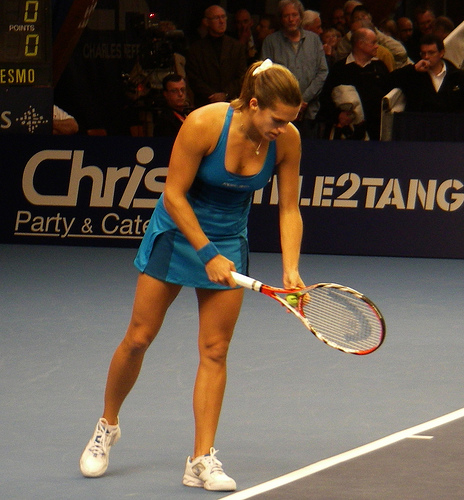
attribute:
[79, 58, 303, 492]
woman — playing, preparing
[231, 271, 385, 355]
racket — present, red, white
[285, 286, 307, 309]
tennis ball — green, present, yellow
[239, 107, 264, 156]
necklace — gold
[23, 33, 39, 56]
points — green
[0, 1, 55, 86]
scoreboard — yellow, black, present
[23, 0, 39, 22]
points — green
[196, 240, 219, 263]
wristband — blue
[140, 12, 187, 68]
camera — recording, filming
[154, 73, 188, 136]
man — sitting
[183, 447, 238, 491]
sneaker — white, grey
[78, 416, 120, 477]
sneaker — white, grey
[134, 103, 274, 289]
outfit — blue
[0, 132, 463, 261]
wall — blue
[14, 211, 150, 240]
writing — white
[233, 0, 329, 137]
people — watching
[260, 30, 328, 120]
shirt — grey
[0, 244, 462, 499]
tennis court — blue, grey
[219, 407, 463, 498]
line — white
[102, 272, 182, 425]
leg — shaved, bare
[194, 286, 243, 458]
leg — shaved, bare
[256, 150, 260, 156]
locket — gold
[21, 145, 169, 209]
writing — white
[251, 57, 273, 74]
headband — white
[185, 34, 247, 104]
blazer — brown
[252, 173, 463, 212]
writing — white